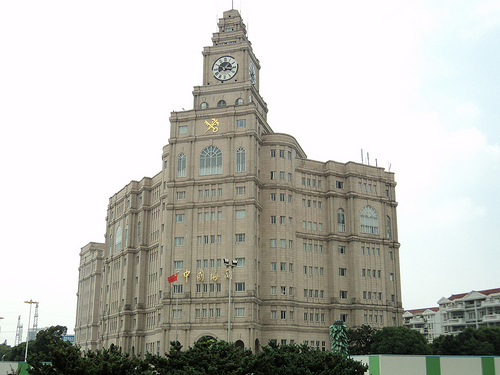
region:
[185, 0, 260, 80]
Top of building with clock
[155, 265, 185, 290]
Flag in front of building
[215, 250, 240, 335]
Streetlight in front of building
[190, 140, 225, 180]
Window on front of building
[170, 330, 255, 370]
Bushes in front of building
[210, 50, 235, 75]
Round clock on top of building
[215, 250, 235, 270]
Streetlights on pole in front of building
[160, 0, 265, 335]
Front of a big building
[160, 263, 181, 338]
Red flag on flagpole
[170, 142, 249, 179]
Three windows on front of building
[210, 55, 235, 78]
a white clock on the top of the building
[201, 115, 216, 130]
a key and health logo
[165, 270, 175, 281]
the peoples republic of China flag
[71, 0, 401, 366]
a beige color building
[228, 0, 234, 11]
a communications antenna on the top of the building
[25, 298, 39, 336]
a construction tower in the distance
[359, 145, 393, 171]
communication antennas on the building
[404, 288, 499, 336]
residential apartments behind the building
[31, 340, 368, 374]
large trees in front of the building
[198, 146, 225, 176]
an arched window on the building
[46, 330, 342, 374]
the trees are infront of the building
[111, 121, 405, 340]
the building has atleast six floors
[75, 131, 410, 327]
the building is full of windows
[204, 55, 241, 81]
it is three oclock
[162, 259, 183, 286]
the color of the flag is red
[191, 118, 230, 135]
the emblem is yellow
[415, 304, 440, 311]
the roof is red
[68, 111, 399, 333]
the building is made of stone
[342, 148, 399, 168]
there are flags on top of the building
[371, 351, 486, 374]
the wall is green and white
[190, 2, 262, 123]
a clock on a building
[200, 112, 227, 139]
gold emblem on a building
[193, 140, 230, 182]
large arched window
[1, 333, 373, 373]
trees at the base of the building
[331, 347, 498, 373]
green and white striped wall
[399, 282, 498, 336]
balconies on building to the right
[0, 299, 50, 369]
towers in the background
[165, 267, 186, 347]
red flag flying out front of the building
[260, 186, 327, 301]
lots of windows on a beige building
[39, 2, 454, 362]
large beige building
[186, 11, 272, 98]
two clocks are visible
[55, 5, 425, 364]
tall and wide building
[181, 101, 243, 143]
golden symbol on building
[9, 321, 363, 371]
green leaves on tree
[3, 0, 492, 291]
sky is white and blue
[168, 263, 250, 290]
golden lettering on building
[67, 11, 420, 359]
building is tan colored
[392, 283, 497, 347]
building with red roof in the background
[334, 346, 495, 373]
fence is green and white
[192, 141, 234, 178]
window has a rounded top